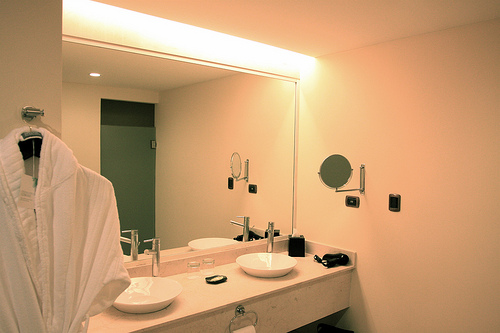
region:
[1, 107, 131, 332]
The robe is hanging on the wall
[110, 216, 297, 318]
There are two sinks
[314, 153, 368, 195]
The mirror is silver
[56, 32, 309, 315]
The large mirror is above the sinks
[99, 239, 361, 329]
The counter is white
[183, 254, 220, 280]
Two clear glass cups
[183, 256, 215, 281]
The cups are upside down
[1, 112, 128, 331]
The robe is white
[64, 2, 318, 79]
The light is long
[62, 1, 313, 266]
The light is above the mirror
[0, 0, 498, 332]
softly lighted hotel bathroom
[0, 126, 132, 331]
new terry cloth bath robe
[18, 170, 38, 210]
price tag on new bath robe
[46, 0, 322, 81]
dome lighting over bathroom mirror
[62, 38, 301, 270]
bathroom mirror over sink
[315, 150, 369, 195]
swing mirror affixed to bathroom wall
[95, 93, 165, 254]
mirror image of green bathroom door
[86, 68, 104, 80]
mirror image of bathroom light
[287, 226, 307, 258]
black box of kleenex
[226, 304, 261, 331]
roll of toilet tissue on spindle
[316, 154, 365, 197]
personal mirror on the wall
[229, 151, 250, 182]
reflection of a personal mirror on the wall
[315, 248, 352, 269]
black hair dryer on the counter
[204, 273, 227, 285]
black soap dish on the counter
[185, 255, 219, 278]
two clear glass cups on the counter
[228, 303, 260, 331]
roll of toilet paper hanging from the counter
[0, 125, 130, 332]
white bath robe hanging from the wall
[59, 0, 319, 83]
fluorescent light above the mirror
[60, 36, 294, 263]
large mirror in the bathroom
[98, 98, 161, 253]
reflection of the shower door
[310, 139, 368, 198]
A mirror hangs on the wall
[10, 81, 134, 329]
A bathrobe hangs on the wall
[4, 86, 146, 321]
The bathrobe is white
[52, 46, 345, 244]
A mirror is on the wall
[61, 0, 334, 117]
A light illuminates the room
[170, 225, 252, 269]
A white vase reflects on the mirror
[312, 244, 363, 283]
A black blow dryer sits on the counter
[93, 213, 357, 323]
The counter is off-white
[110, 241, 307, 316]
There are two glass bowls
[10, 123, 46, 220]
The bathrobe has a tag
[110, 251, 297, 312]
two round sinks in the bathroom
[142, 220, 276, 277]
metal faucets above the sinks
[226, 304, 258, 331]
towel holder below the sinks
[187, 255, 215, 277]
two glasses in between the sinks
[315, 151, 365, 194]
shaving mirror attached to the wall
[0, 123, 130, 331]
a bath robe hanging on the wall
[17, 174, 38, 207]
a tag attached to the bath robe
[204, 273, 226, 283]
a black soap holder in between the sinks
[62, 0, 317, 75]
light coming from the ceiling above the mirror